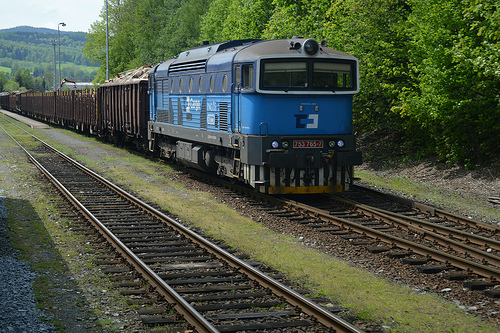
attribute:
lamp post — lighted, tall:
[55, 20, 68, 87]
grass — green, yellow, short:
[336, 272, 400, 313]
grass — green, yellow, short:
[200, 211, 260, 252]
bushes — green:
[358, 9, 498, 150]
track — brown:
[42, 137, 329, 331]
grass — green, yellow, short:
[4, 108, 489, 330]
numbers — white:
[291, 137, 324, 152]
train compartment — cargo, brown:
[67, 80, 102, 137]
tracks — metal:
[7, 137, 367, 329]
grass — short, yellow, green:
[56, 134, 491, 329]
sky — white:
[1, 0, 126, 35]